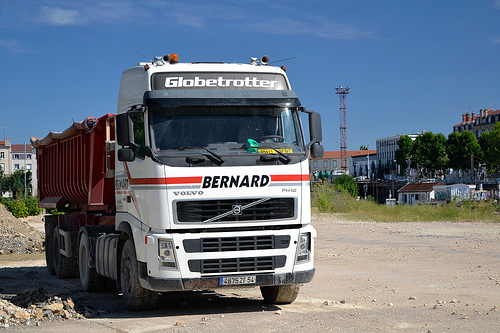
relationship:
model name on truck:
[173, 190, 203, 196] [30, 37, 317, 307]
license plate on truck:
[219, 276, 256, 285] [30, 37, 317, 307]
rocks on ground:
[410, 295, 432, 313] [3, 217, 499, 332]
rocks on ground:
[325, 299, 350, 308] [3, 217, 499, 332]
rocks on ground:
[174, 320, 187, 328] [3, 217, 499, 332]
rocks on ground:
[385, 302, 396, 309] [3, 217, 499, 332]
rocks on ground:
[274, 308, 287, 318] [3, 217, 499, 332]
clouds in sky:
[45, 0, 381, 40] [1, 0, 498, 150]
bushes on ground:
[1, 194, 40, 217] [3, 217, 499, 332]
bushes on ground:
[334, 175, 358, 196] [3, 217, 499, 332]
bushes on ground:
[313, 184, 356, 211] [3, 217, 499, 332]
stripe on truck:
[125, 176, 313, 184] [30, 37, 317, 307]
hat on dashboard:
[245, 138, 259, 155] [154, 141, 298, 153]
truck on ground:
[30, 37, 317, 307] [3, 217, 499, 332]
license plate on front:
[219, 276, 256, 285] [151, 73, 306, 284]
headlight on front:
[158, 238, 179, 274] [151, 73, 306, 284]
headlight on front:
[295, 234, 312, 267] [151, 73, 306, 284]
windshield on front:
[152, 104, 306, 167] [151, 73, 306, 284]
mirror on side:
[119, 150, 134, 163] [117, 104, 165, 236]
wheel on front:
[119, 239, 162, 311] [151, 73, 306, 284]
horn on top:
[160, 55, 176, 65] [123, 62, 291, 90]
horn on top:
[259, 56, 271, 65] [123, 62, 291, 90]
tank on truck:
[125, 196, 133, 202] [30, 37, 317, 307]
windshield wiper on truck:
[198, 146, 227, 163] [30, 37, 317, 307]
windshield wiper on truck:
[265, 143, 291, 163] [30, 37, 317, 307]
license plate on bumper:
[219, 276, 256, 285] [150, 269, 317, 292]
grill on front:
[172, 200, 297, 272] [151, 73, 306, 284]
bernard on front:
[201, 176, 269, 187] [151, 73, 306, 284]